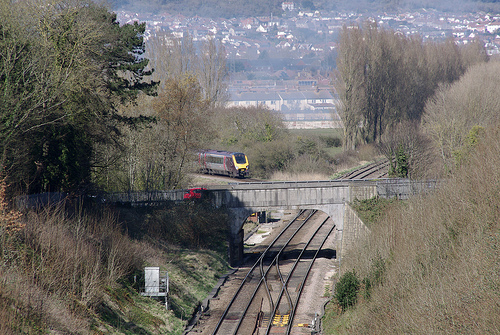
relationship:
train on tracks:
[204, 146, 254, 176] [261, 239, 303, 296]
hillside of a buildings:
[242, 47, 301, 78] [144, 13, 471, 83]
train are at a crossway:
[204, 146, 254, 176] [228, 167, 334, 239]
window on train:
[235, 155, 247, 165] [176, 147, 252, 177]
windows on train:
[201, 154, 226, 164] [193, 144, 252, 178]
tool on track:
[271, 312, 291, 326] [185, 132, 465, 331]